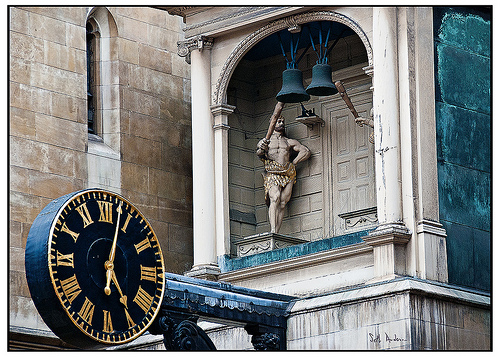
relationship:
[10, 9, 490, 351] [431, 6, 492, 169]
building has marks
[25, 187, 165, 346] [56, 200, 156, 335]
clock has roman numerals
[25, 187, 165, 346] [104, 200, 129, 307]
clock has hands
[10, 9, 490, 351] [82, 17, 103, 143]
building has a window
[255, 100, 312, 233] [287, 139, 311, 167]
statue has arm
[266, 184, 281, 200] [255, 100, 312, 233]
thigh on statue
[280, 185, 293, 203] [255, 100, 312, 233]
thigh on statue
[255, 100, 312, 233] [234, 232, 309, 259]
statue on pedestal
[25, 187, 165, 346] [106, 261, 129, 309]
clock has hour hand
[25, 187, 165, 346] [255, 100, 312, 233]
clock near statue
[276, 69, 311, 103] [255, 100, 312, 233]
bell are above statue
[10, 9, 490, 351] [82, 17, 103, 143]
building has window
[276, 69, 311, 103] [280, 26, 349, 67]
bell are connected to ropes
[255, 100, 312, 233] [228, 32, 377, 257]
statue near a wall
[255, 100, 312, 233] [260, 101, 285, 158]
statue holding weapon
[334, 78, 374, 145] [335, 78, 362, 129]
statue holding weapon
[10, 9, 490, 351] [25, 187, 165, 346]
building has a clock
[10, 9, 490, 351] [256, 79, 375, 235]
building has statues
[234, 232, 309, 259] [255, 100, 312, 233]
pedestal beneath statue